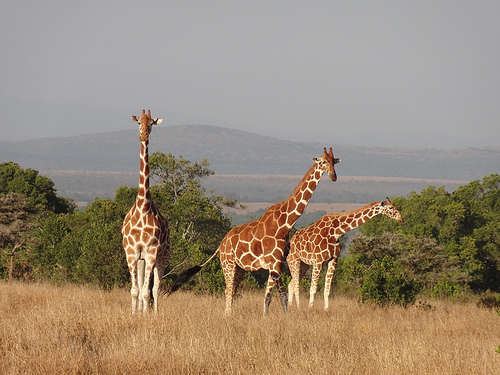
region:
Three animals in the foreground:
[110, 93, 412, 334]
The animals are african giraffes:
[103, 104, 417, 326]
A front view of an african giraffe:
[111, 104, 182, 321]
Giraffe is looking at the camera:
[122, 102, 163, 162]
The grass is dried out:
[2, 294, 499, 374]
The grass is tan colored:
[3, 287, 499, 371]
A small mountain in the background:
[14, 116, 305, 171]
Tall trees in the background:
[0, 150, 499, 310]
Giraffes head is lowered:
[308, 171, 418, 303]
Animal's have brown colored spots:
[108, 103, 410, 318]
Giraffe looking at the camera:
[121, 110, 168, 312]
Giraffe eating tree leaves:
[286, 201, 405, 308]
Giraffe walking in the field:
[165, 145, 341, 311]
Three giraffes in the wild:
[119, 110, 410, 310]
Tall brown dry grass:
[0, 280, 499, 374]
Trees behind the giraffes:
[1, 155, 497, 300]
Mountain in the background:
[0, 125, 497, 175]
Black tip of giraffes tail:
[166, 263, 197, 298]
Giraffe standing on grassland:
[121, 111, 170, 317]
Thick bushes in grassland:
[344, 174, 499, 305]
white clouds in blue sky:
[17, 14, 83, 60]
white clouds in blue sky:
[17, 63, 75, 88]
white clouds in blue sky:
[23, 89, 111, 122]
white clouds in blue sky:
[109, 13, 190, 51]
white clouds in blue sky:
[118, 60, 186, 92]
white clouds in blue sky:
[215, 17, 287, 67]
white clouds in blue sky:
[304, 30, 397, 84]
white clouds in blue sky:
[400, 87, 476, 124]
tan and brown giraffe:
[110, 105, 177, 310]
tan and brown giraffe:
[332, 193, 408, 250]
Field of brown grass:
[0, 281, 499, 373]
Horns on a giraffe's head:
[140, 110, 152, 117]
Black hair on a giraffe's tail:
[161, 262, 205, 297]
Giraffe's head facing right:
[376, 196, 407, 224]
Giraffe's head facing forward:
[129, 110, 163, 142]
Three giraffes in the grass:
[114, 106, 409, 328]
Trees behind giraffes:
[3, 150, 496, 312]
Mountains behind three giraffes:
[5, 121, 499, 183]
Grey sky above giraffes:
[2, 2, 499, 149]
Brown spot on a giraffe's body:
[232, 239, 250, 260]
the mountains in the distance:
[1, 93, 499, 183]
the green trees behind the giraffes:
[0, 160, 499, 307]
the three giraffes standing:
[122, 109, 404, 309]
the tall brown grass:
[0, 277, 498, 374]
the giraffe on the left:
[120, 108, 170, 315]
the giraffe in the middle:
[163, 147, 340, 316]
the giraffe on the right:
[285, 196, 403, 313]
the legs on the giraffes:
[126, 258, 338, 314]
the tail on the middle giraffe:
[161, 238, 221, 298]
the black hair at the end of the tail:
[165, 264, 201, 299]